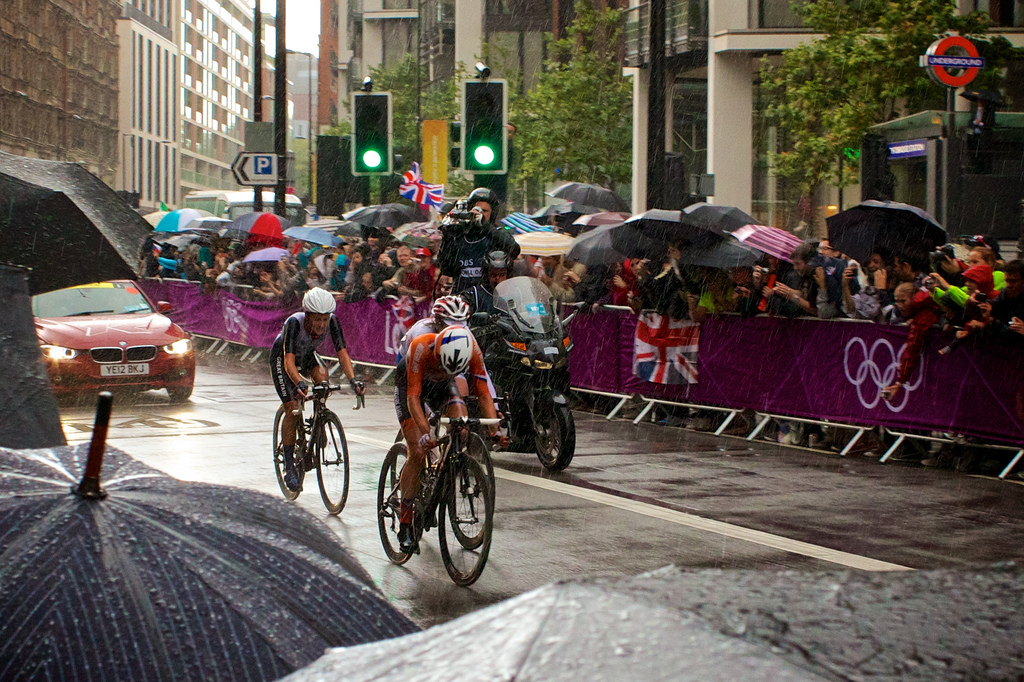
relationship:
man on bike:
[403, 321, 501, 432] [396, 437, 512, 546]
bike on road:
[396, 437, 512, 546] [603, 434, 745, 544]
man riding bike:
[403, 321, 501, 432] [396, 437, 512, 546]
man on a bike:
[403, 321, 501, 432] [396, 437, 512, 546]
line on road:
[607, 474, 688, 535] [603, 434, 745, 544]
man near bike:
[403, 321, 501, 432] [396, 437, 512, 546]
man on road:
[403, 321, 501, 432] [603, 434, 745, 544]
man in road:
[403, 321, 501, 432] [603, 434, 745, 544]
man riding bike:
[391, 295, 498, 553] [373, 393, 516, 587]